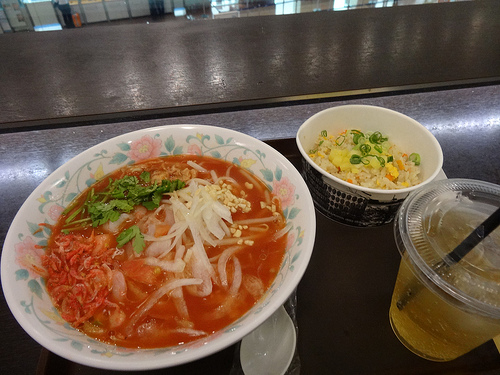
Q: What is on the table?
A: Food.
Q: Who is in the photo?
A: Nobody.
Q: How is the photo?
A: Clear.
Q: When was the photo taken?
A: During the day.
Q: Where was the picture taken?
A: At a restaurant.